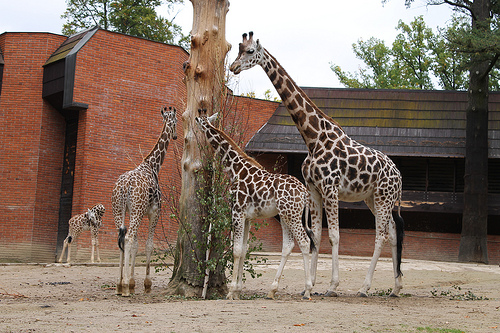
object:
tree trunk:
[165, 1, 235, 296]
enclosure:
[0, 32, 494, 329]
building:
[0, 25, 283, 266]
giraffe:
[110, 105, 178, 298]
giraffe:
[227, 32, 405, 297]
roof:
[243, 83, 500, 158]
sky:
[0, 0, 498, 101]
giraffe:
[55, 201, 108, 265]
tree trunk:
[443, 1, 497, 264]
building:
[243, 87, 500, 234]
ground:
[2, 247, 494, 332]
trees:
[330, 16, 436, 91]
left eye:
[243, 46, 256, 56]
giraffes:
[189, 109, 320, 298]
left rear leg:
[351, 190, 391, 297]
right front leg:
[299, 191, 326, 294]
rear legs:
[65, 229, 81, 265]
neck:
[93, 202, 110, 219]